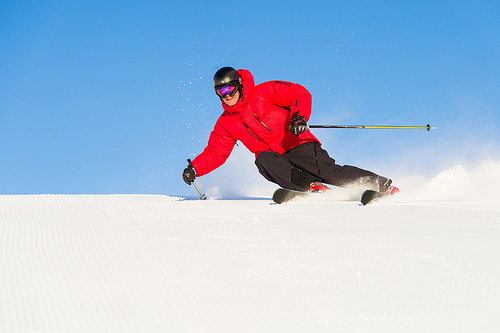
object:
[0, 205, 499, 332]
snow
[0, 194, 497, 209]
lines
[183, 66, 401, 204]
man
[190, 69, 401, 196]
red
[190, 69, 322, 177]
sweatshirt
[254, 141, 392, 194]
pants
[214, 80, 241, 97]
goggles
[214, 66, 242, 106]
head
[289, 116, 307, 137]
glove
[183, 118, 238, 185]
arm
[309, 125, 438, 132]
pole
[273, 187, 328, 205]
skis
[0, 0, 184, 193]
sky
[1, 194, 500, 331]
ground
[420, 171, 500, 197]
snow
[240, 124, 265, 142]
strings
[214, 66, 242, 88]
helmet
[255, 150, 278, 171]
knee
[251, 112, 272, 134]
zipper